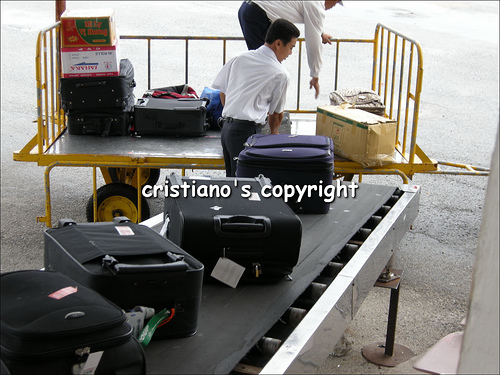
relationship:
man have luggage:
[210, 17, 304, 177] [167, 135, 338, 279]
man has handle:
[219, 21, 299, 145] [273, 181, 318, 202]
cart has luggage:
[16, 16, 447, 182] [67, 75, 205, 144]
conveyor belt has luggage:
[208, 173, 400, 346] [167, 135, 338, 279]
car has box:
[16, 16, 447, 182] [315, 100, 396, 163]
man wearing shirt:
[219, 21, 299, 145] [218, 45, 280, 116]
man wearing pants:
[219, 21, 299, 145] [221, 121, 251, 178]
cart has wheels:
[16, 16, 447, 182] [91, 161, 157, 220]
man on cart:
[240, 0, 335, 57] [16, 16, 447, 182]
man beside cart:
[219, 21, 299, 145] [16, 16, 447, 182]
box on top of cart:
[315, 100, 396, 163] [16, 16, 447, 182]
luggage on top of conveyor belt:
[167, 135, 338, 279] [131, 178, 401, 375]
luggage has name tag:
[167, 135, 338, 279] [208, 254, 253, 294]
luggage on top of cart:
[67, 75, 205, 144] [16, 16, 447, 182]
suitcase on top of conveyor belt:
[159, 170, 302, 286] [131, 178, 401, 375]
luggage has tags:
[167, 135, 338, 279] [208, 254, 253, 294]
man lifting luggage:
[219, 21, 299, 145] [167, 135, 338, 279]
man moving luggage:
[219, 21, 299, 145] [167, 135, 338, 279]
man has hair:
[219, 21, 299, 145] [266, 15, 302, 50]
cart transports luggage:
[16, 16, 447, 182] [67, 75, 205, 144]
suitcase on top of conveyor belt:
[239, 132, 338, 206] [131, 178, 401, 375]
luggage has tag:
[1, 274, 138, 375] [48, 285, 79, 303]